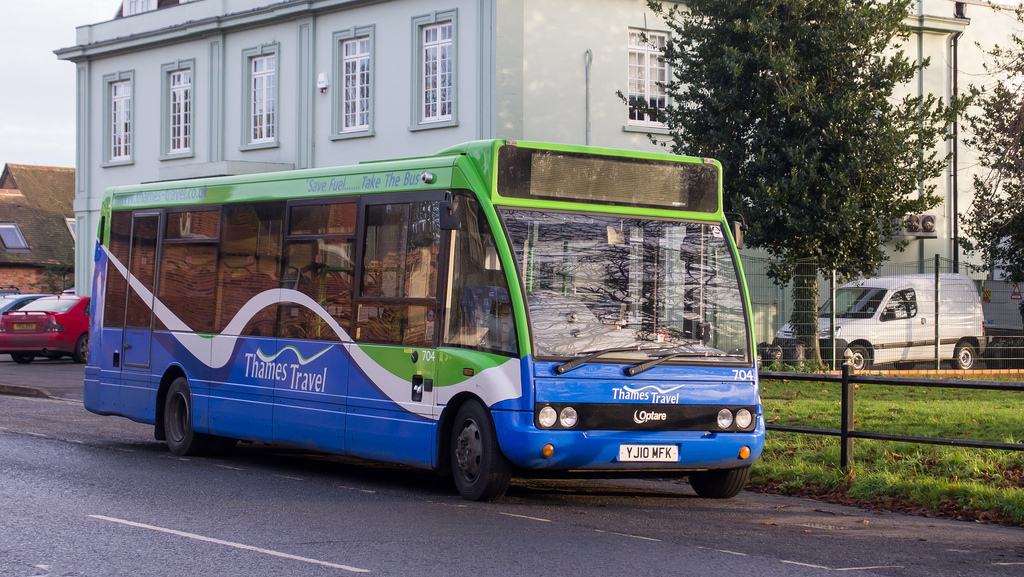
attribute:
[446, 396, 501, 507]
tire —  bus', the front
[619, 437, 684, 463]
license plate — black, white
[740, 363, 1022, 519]
grass — green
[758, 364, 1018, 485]
fence — black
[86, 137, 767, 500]
bus — green, blue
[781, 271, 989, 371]
van — white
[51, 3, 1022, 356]
building — grey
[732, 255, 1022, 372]
fence — tall, wired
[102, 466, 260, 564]
line — white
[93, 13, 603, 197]
windows — white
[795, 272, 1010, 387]
van — grey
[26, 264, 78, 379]
car — red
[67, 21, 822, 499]
bus — blue, green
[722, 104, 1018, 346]
leaves — green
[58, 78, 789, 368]
building — white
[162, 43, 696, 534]
bus — blue, green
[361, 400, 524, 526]
wheel — black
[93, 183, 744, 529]
bus — blue, green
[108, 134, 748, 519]
bus — blue and green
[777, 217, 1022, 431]
van — white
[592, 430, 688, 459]
plate — license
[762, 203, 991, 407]
car — red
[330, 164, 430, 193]
lettering — blue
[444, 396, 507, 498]
wheel — black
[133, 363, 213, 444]
tire — black